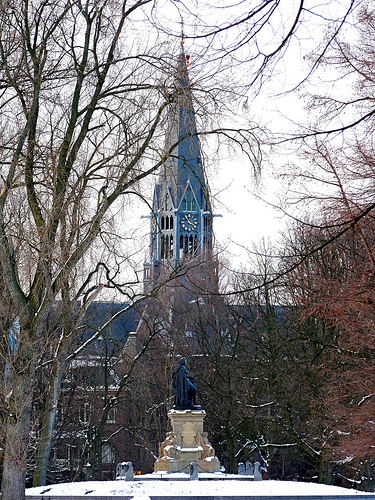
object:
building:
[143, 19, 221, 354]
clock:
[176, 207, 204, 235]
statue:
[166, 353, 208, 411]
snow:
[26, 475, 374, 500]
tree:
[40, 2, 267, 231]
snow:
[142, 478, 257, 496]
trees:
[0, 238, 342, 425]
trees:
[1, 0, 131, 483]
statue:
[171, 353, 202, 409]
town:
[0, 1, 374, 497]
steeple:
[142, 5, 222, 300]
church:
[0, 285, 318, 471]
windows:
[51, 393, 122, 422]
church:
[16, 287, 330, 481]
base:
[149, 455, 222, 472]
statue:
[153, 352, 221, 470]